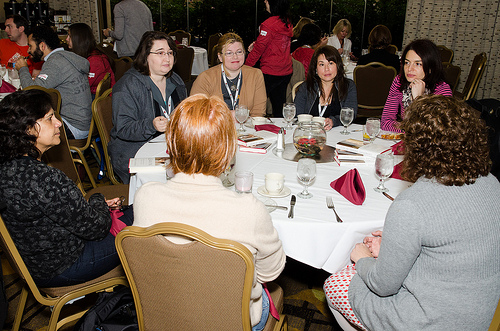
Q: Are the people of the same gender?
A: No, they are both male and female.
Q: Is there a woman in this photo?
A: Yes, there is a woman.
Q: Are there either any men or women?
A: Yes, there is a woman.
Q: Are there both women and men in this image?
A: Yes, there are both a woman and a man.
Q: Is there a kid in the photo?
A: No, there are no children.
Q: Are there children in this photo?
A: No, there are no children.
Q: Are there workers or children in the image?
A: No, there are no children or workers.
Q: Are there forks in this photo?
A: Yes, there is a fork.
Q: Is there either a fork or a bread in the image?
A: Yes, there is a fork.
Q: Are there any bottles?
A: No, there are no bottles.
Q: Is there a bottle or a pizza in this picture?
A: No, there are no bottles or pizzas.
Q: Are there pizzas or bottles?
A: No, there are no bottles or pizzas.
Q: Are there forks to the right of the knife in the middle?
A: Yes, there is a fork to the right of the knife.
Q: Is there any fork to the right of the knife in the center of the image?
A: Yes, there is a fork to the right of the knife.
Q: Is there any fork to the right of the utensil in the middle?
A: Yes, there is a fork to the right of the knife.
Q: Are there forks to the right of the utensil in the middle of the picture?
A: Yes, there is a fork to the right of the knife.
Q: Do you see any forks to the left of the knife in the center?
A: No, the fork is to the right of the knife.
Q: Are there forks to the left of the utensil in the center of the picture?
A: No, the fork is to the right of the knife.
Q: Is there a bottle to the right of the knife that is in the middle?
A: No, there is a fork to the right of the knife.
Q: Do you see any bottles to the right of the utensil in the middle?
A: No, there is a fork to the right of the knife.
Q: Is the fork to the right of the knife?
A: Yes, the fork is to the right of the knife.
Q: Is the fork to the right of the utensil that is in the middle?
A: Yes, the fork is to the right of the knife.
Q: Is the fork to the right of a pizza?
A: No, the fork is to the right of the knife.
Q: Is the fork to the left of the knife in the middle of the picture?
A: No, the fork is to the right of the knife.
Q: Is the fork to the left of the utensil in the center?
A: No, the fork is to the right of the knife.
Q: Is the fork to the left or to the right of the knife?
A: The fork is to the right of the knife.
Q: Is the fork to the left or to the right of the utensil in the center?
A: The fork is to the right of the knife.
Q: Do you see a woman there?
A: Yes, there is a woman.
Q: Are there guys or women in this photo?
A: Yes, there is a woman.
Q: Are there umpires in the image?
A: No, there are no umpires.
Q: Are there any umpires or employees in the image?
A: No, there are no umpires or employees.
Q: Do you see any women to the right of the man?
A: Yes, there is a woman to the right of the man.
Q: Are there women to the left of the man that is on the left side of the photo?
A: No, the woman is to the right of the man.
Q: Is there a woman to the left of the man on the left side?
A: No, the woman is to the right of the man.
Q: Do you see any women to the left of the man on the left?
A: No, the woman is to the right of the man.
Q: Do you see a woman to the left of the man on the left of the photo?
A: No, the woman is to the right of the man.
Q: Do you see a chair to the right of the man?
A: No, there is a woman to the right of the man.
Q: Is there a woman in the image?
A: Yes, there is a woman.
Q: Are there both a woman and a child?
A: No, there is a woman but no children.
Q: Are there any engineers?
A: No, there are no engineers.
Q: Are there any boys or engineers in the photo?
A: No, there are no engineers or boys.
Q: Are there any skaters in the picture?
A: No, there are no skaters.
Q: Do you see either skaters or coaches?
A: No, there are no skaters or coaches.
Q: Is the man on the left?
A: Yes, the man is on the left of the image.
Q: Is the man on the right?
A: No, the man is on the left of the image.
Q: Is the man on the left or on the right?
A: The man is on the left of the image.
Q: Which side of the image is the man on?
A: The man is on the left of the image.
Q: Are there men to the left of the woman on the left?
A: Yes, there is a man to the left of the woman.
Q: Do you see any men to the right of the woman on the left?
A: No, the man is to the left of the woman.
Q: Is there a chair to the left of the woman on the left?
A: No, there is a man to the left of the woman.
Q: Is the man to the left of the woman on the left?
A: Yes, the man is to the left of the woman.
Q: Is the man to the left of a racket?
A: No, the man is to the left of the woman.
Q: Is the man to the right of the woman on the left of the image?
A: No, the man is to the left of the woman.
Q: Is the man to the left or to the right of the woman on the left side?
A: The man is to the left of the woman.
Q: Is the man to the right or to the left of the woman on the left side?
A: The man is to the left of the woman.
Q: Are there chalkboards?
A: No, there are no chalkboards.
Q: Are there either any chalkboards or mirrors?
A: No, there are no chalkboards or mirrors.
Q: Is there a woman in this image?
A: Yes, there is a woman.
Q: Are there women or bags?
A: Yes, there is a woman.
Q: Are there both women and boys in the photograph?
A: No, there is a woman but no boys.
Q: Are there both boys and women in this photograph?
A: No, there is a woman but no boys.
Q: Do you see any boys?
A: No, there are no boys.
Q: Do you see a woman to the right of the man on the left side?
A: Yes, there is a woman to the right of the man.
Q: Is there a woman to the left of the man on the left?
A: No, the woman is to the right of the man.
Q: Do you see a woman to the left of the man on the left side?
A: No, the woman is to the right of the man.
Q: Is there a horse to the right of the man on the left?
A: No, there is a woman to the right of the man.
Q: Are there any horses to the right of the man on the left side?
A: No, there is a woman to the right of the man.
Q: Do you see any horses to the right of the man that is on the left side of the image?
A: No, there is a woman to the right of the man.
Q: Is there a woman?
A: Yes, there is a woman.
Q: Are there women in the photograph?
A: Yes, there is a woman.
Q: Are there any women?
A: Yes, there is a woman.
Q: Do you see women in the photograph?
A: Yes, there is a woman.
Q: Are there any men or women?
A: Yes, there is a woman.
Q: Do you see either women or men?
A: Yes, there is a woman.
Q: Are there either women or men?
A: Yes, there is a woman.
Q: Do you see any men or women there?
A: Yes, there is a woman.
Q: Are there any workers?
A: No, there are no workers.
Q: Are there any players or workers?
A: No, there are no workers or players.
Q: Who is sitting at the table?
A: The woman is sitting at the table.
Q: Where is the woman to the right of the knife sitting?
A: The woman is sitting at the table.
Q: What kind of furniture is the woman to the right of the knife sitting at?
A: The woman is sitting at the table.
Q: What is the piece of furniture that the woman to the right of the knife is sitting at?
A: The piece of furniture is a table.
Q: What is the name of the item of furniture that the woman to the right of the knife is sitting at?
A: The piece of furniture is a table.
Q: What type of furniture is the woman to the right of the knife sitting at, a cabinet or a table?
A: The woman is sitting at a table.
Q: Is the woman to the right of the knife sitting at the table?
A: Yes, the woman is sitting at the table.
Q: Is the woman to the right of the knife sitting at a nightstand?
A: No, the woman is sitting at the table.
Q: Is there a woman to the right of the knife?
A: Yes, there is a woman to the right of the knife.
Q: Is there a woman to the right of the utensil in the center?
A: Yes, there is a woman to the right of the knife.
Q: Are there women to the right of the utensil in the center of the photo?
A: Yes, there is a woman to the right of the knife.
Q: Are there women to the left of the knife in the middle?
A: No, the woman is to the right of the knife.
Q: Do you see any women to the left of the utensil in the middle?
A: No, the woman is to the right of the knife.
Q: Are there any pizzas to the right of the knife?
A: No, there is a woman to the right of the knife.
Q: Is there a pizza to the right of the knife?
A: No, there is a woman to the right of the knife.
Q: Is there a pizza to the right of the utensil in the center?
A: No, there is a woman to the right of the knife.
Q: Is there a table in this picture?
A: Yes, there is a table.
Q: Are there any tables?
A: Yes, there is a table.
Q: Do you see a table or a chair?
A: Yes, there is a table.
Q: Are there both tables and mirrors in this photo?
A: No, there is a table but no mirrors.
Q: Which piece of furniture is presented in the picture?
A: The piece of furniture is a table.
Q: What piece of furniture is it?
A: The piece of furniture is a table.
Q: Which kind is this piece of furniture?
A: This is a table.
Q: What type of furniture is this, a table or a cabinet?
A: This is a table.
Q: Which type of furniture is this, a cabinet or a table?
A: This is a table.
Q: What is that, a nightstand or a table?
A: That is a table.